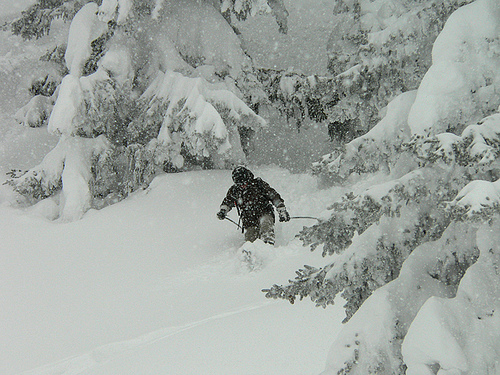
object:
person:
[217, 165, 289, 246]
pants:
[243, 213, 275, 242]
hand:
[278, 212, 288, 222]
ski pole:
[278, 215, 323, 222]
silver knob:
[243, 210, 280, 247]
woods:
[23, 1, 212, 184]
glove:
[277, 213, 289, 222]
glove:
[216, 210, 227, 220]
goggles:
[230, 168, 252, 185]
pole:
[288, 216, 322, 223]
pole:
[224, 215, 242, 227]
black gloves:
[215, 209, 227, 221]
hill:
[0, 163, 348, 371]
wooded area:
[0, 0, 499, 373]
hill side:
[0, 171, 499, 371]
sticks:
[216, 204, 333, 239]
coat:
[220, 178, 284, 229]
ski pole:
[222, 214, 243, 229]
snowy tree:
[11, 0, 262, 222]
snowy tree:
[267, 126, 499, 369]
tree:
[0, 0, 213, 224]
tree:
[260, 0, 497, 371]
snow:
[0, 146, 351, 373]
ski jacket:
[221, 163, 286, 223]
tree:
[284, 56, 498, 186]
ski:
[214, 131, 308, 273]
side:
[0, 143, 139, 294]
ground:
[0, 174, 406, 375]